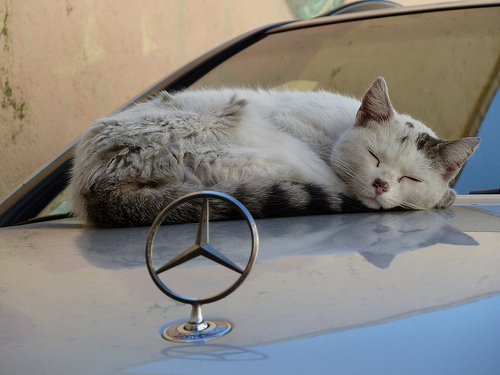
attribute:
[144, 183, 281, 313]
insignia — round, metallic gray, mercedes, silver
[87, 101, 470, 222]
cat — sleeping, lying on car, furry, long haired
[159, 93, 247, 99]
fur — light gray, gray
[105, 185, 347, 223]
tail — gray, black, light, dark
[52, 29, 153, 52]
wall — brown, dirty, cream colored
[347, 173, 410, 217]
snout — short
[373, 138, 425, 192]
eyes — closed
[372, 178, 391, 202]
nose — pink